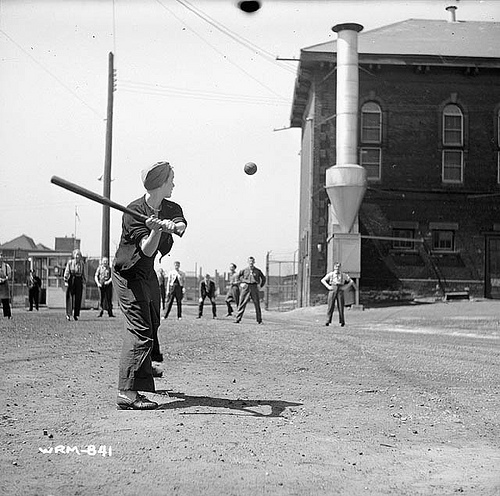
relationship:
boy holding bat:
[105, 152, 186, 418] [43, 174, 182, 236]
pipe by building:
[323, 18, 373, 291] [270, 4, 499, 310]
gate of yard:
[266, 249, 305, 313] [5, 300, 500, 495]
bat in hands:
[43, 174, 182, 236] [144, 214, 179, 235]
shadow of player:
[155, 386, 305, 424] [105, 152, 186, 418]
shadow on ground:
[155, 386, 305, 424] [5, 300, 500, 495]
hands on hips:
[321, 284, 351, 293] [328, 284, 346, 293]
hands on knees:
[200, 295, 220, 304] [197, 294, 216, 306]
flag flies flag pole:
[77, 211, 82, 223] [72, 205, 80, 252]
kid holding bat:
[105, 152, 186, 418] [43, 174, 182, 236]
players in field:
[5, 252, 272, 318] [5, 300, 500, 495]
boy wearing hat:
[105, 152, 186, 418] [136, 159, 175, 192]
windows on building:
[427, 96, 477, 187] [270, 4, 499, 310]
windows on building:
[353, 87, 389, 185] [270, 4, 499, 310]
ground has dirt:
[5, 300, 500, 495] [374, 384, 491, 481]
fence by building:
[266, 249, 305, 313] [270, 4, 499, 310]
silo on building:
[323, 18, 373, 291] [270, 4, 499, 310]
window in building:
[437, 101, 466, 149] [270, 4, 499, 310]